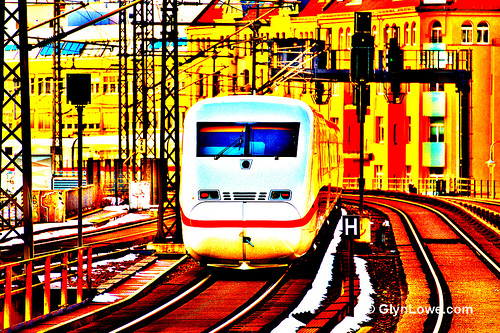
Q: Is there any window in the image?
A: Yes, there is a window.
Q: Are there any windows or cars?
A: Yes, there is a window.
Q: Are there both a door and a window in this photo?
A: No, there is a window but no doors.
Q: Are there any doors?
A: No, there are no doors.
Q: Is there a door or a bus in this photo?
A: No, there are no doors or buses.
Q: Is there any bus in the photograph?
A: No, there are no buses.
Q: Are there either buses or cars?
A: No, there are no buses or cars.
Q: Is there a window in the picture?
A: Yes, there is a window.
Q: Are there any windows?
A: Yes, there is a window.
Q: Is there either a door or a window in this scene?
A: Yes, there is a window.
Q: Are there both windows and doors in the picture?
A: No, there is a window but no doors.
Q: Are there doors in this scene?
A: No, there are no doors.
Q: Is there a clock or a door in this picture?
A: No, there are no doors or clocks.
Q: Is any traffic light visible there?
A: Yes, there is a traffic light.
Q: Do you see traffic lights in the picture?
A: Yes, there is a traffic light.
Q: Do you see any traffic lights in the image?
A: Yes, there is a traffic light.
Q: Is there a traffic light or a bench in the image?
A: Yes, there is a traffic light.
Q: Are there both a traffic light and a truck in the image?
A: No, there is a traffic light but no trucks.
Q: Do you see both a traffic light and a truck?
A: No, there is a traffic light but no trucks.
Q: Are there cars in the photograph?
A: No, there are no cars.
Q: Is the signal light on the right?
A: Yes, the signal light is on the right of the image.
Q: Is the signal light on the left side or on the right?
A: The signal light is on the right of the image.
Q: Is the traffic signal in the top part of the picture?
A: Yes, the traffic signal is in the top of the image.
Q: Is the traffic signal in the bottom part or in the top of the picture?
A: The traffic signal is in the top of the image.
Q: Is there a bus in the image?
A: No, there are no buses.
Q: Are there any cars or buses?
A: No, there are no buses or cars.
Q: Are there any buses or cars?
A: No, there are no buses or cars.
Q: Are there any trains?
A: Yes, there is a train.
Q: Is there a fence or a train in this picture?
A: Yes, there is a train.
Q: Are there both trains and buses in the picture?
A: No, there is a train but no buses.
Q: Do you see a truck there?
A: No, there are no trucks.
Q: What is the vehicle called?
A: The vehicle is a train.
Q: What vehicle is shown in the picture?
A: The vehicle is a train.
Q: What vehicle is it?
A: The vehicle is a train.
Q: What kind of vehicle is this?
A: This is a train.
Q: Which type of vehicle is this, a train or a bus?
A: This is a train.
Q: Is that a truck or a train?
A: That is a train.